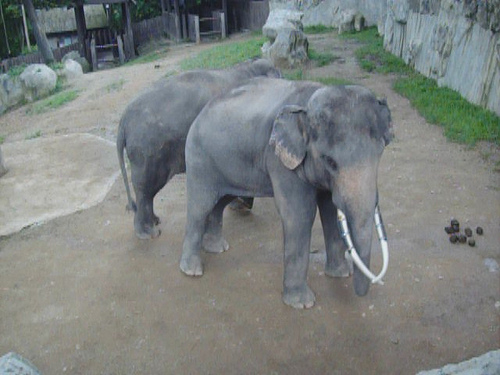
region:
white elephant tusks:
[331, 190, 413, 310]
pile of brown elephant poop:
[411, 206, 498, 263]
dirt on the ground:
[48, 242, 158, 325]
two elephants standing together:
[93, 38, 449, 320]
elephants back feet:
[158, 215, 238, 293]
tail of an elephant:
[105, 119, 135, 285]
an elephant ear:
[234, 84, 331, 200]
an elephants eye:
[310, 125, 355, 191]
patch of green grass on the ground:
[386, 46, 481, 165]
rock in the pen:
[0, 45, 89, 104]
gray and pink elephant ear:
[235, 95, 337, 187]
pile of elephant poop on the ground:
[437, 212, 487, 261]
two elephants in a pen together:
[88, 40, 426, 344]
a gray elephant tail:
[104, 119, 146, 243]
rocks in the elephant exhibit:
[20, 53, 74, 102]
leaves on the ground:
[330, 289, 415, 348]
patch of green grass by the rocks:
[377, 40, 491, 157]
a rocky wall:
[397, 7, 493, 82]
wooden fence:
[71, 7, 194, 82]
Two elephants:
[110, 61, 395, 311]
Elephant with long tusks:
[275, 81, 393, 311]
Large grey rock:
[257, 5, 319, 72]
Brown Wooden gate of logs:
[66, 22, 140, 75]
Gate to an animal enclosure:
[142, 0, 245, 72]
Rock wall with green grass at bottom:
[267, 1, 499, 117]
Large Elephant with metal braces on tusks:
[175, 75, 402, 318]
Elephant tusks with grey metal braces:
[322, 199, 407, 291]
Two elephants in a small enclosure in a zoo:
[4, 15, 492, 364]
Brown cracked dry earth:
[0, 131, 109, 297]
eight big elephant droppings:
[445, 214, 485, 249]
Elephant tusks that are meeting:
[330, 203, 415, 310]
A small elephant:
[183, 75, 400, 312]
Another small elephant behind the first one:
[98, 56, 191, 226]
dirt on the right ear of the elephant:
[262, 127, 318, 189]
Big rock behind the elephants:
[256, 10, 323, 82]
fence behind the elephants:
[6, 27, 219, 71]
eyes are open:
[313, 142, 348, 179]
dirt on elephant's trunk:
[333, 167, 411, 300]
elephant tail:
[96, 118, 165, 240]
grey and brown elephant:
[175, 76, 398, 319]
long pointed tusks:
[337, 206, 397, 287]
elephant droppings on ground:
[441, 207, 490, 250]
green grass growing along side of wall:
[349, 25, 485, 145]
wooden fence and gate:
[77, 7, 228, 62]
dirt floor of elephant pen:
[27, 172, 234, 369]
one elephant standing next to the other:
[95, 47, 292, 242]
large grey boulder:
[258, 3, 318, 83]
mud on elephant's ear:
[266, 129, 313, 178]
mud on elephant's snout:
[339, 156, 378, 229]